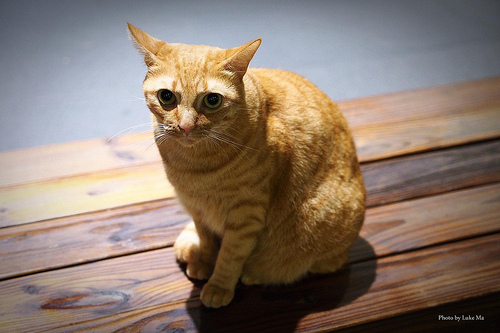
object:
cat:
[127, 22, 366, 308]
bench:
[2, 76, 499, 331]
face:
[144, 68, 238, 147]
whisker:
[206, 128, 263, 153]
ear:
[219, 38, 261, 86]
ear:
[127, 22, 168, 62]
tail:
[173, 219, 203, 263]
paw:
[183, 257, 215, 279]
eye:
[202, 92, 223, 110]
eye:
[155, 89, 178, 107]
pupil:
[207, 93, 219, 105]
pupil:
[161, 89, 173, 101]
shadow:
[177, 233, 378, 331]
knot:
[40, 292, 125, 308]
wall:
[1, 1, 499, 149]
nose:
[178, 124, 196, 134]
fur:
[264, 90, 326, 148]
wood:
[1, 180, 136, 329]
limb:
[200, 190, 267, 307]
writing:
[436, 313, 486, 320]